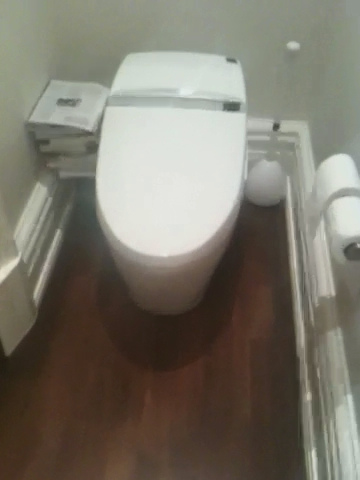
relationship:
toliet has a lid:
[97, 51, 250, 317] [93, 106, 247, 254]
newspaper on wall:
[27, 69, 111, 180] [0, 1, 359, 442]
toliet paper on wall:
[302, 151, 359, 272] [0, 1, 359, 442]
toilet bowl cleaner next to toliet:
[243, 120, 287, 209] [97, 51, 250, 317]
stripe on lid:
[106, 91, 245, 114] [93, 106, 247, 254]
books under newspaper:
[43, 141, 98, 182] [27, 69, 111, 180]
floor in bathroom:
[1, 199, 303, 479] [2, 2, 357, 479]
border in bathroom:
[2, 116, 359, 478] [2, 2, 357, 479]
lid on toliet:
[93, 106, 247, 254] [97, 51, 250, 317]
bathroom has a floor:
[2, 2, 357, 479] [1, 199, 303, 479]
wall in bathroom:
[0, 1, 359, 442] [2, 2, 357, 479]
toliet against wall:
[97, 51, 250, 317] [0, 1, 359, 442]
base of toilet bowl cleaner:
[249, 158, 285, 207] [243, 120, 287, 209]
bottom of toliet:
[107, 242, 233, 317] [97, 51, 250, 317]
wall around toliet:
[0, 1, 359, 442] [97, 51, 250, 317]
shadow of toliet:
[96, 260, 239, 370] [97, 51, 250, 317]